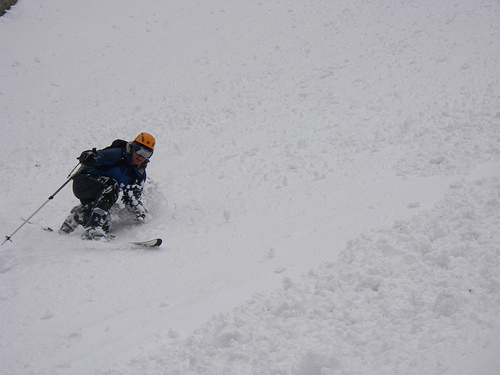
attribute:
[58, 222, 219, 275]
skis — white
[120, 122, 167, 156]
orange hat — helmet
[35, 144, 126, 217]
pole — metal